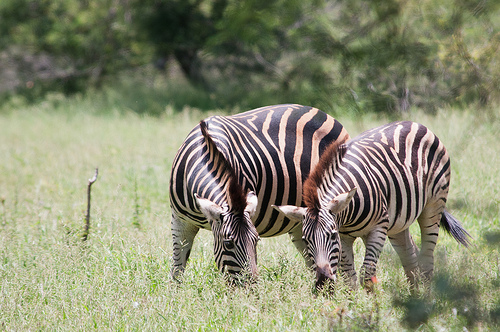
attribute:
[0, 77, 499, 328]
grass — grey, dry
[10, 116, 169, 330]
grass — tall, green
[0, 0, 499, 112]
trees — blurry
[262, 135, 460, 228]
zebra — standing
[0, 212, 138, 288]
grass — dry, grey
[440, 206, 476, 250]
tail — bushy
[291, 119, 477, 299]
zebra — white, black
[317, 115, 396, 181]
ground — grey, dry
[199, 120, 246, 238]
hair — spiked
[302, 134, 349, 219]
hair — spiked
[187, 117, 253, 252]
mane — thick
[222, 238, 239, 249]
eye — black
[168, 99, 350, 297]
zebra — black, white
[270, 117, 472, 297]
zebra — small, black, white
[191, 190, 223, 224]
ears — folded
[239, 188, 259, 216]
ears — folded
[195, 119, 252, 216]
mane — thick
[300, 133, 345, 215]
mane — thick